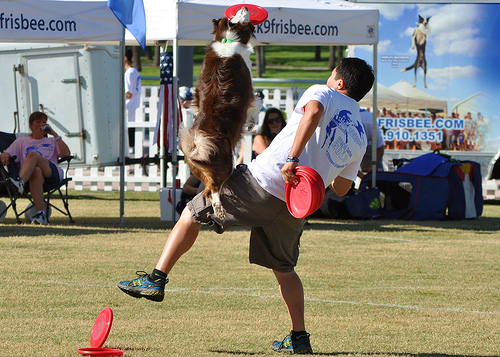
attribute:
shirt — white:
[259, 89, 361, 208]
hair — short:
[340, 60, 375, 98]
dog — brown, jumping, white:
[155, 8, 276, 217]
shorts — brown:
[200, 175, 304, 290]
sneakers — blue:
[119, 273, 169, 305]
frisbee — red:
[68, 314, 120, 357]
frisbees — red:
[284, 166, 334, 219]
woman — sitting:
[5, 109, 80, 224]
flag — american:
[152, 38, 187, 190]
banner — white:
[169, 4, 386, 45]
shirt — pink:
[8, 135, 68, 170]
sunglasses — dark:
[265, 117, 284, 126]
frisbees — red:
[66, 305, 135, 352]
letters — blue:
[266, 19, 341, 40]